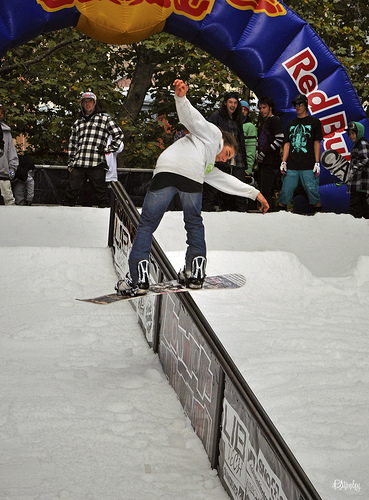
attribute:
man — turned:
[115, 78, 270, 288]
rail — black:
[109, 182, 320, 499]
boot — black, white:
[116, 259, 150, 295]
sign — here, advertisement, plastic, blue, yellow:
[3, 1, 365, 214]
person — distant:
[69, 91, 123, 209]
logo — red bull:
[280, 45, 352, 166]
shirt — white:
[153, 95, 261, 201]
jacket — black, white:
[67, 112, 123, 171]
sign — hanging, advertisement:
[159, 276, 220, 442]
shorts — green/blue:
[279, 169, 320, 206]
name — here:
[331, 476, 363, 495]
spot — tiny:
[143, 462, 155, 475]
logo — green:
[204, 159, 214, 176]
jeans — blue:
[128, 186, 209, 285]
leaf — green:
[142, 44, 155, 51]